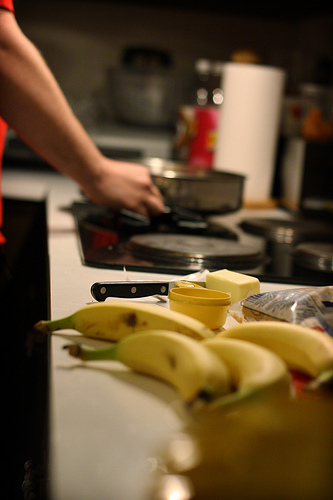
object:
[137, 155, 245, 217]
pot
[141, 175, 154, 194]
knuckles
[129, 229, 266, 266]
stove cover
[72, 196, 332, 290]
stove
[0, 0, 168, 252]
person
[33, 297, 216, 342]
banana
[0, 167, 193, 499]
table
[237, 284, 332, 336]
bag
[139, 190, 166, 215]
finger